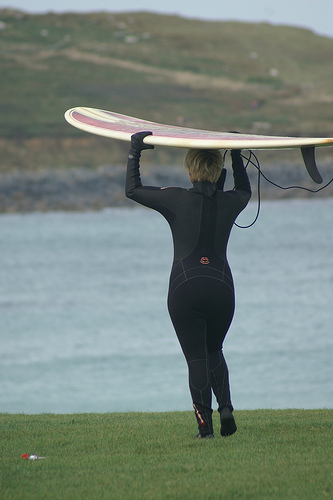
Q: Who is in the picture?
A: A woman.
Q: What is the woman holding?
A: A surfboard.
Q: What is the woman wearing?
A: A wet suit.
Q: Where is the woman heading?
A: Towards water.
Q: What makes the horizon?
A: Hill.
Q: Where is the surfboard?
A: On surfer's head.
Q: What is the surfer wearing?
A: Wetsuit.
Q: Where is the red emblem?
A: On wetsuit.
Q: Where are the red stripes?
A: On surfboard.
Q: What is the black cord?
A: Surfboard leash.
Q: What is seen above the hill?
A: Sky.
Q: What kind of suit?
A: Wetsuit.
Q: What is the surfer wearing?
A: Wetsuit.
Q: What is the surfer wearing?
A: Wetsuit.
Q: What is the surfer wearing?
A: Wetsuit.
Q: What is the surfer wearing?
A: Wetsuit.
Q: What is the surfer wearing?
A: Wetsuit.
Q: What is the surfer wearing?
A: Wetsuit.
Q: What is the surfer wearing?
A: Wetsuit.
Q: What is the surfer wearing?
A: Wetsuit.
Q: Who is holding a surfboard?
A: The woman.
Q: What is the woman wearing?
A: A wetsuit.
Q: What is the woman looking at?
A: Water.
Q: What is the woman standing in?
A: Grass.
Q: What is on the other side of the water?
A: A hill.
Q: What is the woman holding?
A: A surfboard?.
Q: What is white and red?
A: The surfboard.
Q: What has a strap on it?
A: The surfboard.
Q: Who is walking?
A: The woman.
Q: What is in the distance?
A: A hill.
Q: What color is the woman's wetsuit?
A: Black.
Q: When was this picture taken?
A: Daytime.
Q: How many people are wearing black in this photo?
A: One.